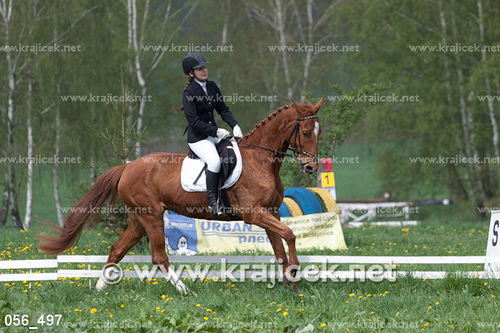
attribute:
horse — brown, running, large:
[33, 90, 330, 301]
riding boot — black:
[205, 168, 224, 212]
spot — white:
[307, 109, 320, 140]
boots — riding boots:
[197, 137, 247, 221]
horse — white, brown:
[73, 103, 348, 282]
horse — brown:
[18, 39, 367, 299]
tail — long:
[31, 166, 125, 261]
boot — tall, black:
[203, 153, 228, 212]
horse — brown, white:
[40, 77, 338, 324]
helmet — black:
[182, 54, 209, 76]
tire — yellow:
[310, 181, 344, 222]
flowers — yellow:
[0, 279, 440, 325]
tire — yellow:
[306, 180, 341, 220]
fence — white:
[0, 253, 497, 284]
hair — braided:
[182, 67, 194, 93]